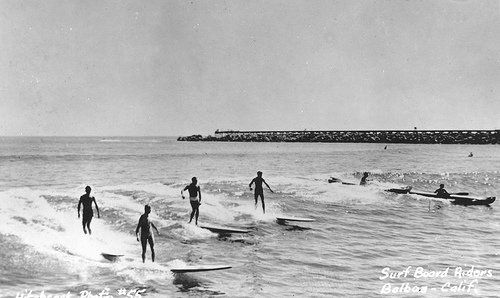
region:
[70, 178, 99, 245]
THIS IS A PERSON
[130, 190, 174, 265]
THIS IS A PERSON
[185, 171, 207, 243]
THIS IS A PERSON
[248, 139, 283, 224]
THIS IS A PERSON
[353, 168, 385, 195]
THIS IS A PERSON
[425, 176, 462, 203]
THIS IS A PERSON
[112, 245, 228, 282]
THAT IS A SURF BOARD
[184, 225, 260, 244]
THAT IS A SURF BOARD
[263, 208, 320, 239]
THAT IS A SURF BOARD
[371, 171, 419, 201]
THAT IS A SURF BOARD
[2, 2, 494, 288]
black and white filter.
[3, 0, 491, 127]
the sky is clear.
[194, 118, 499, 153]
bridge in the background.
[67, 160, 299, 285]
people standing on surf boards.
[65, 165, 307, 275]
people in the ocean.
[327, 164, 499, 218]
people are boating.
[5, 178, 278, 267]
the waves are white.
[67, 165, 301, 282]
four people are surfing.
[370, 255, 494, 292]
white text on the photo.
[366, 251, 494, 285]
text says surf board riders.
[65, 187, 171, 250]
surfers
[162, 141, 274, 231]
surfers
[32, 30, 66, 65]
white clouds in blue sky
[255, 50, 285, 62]
white clouds in blue sky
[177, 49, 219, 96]
white clouds in blue sky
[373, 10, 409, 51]
white clouds in blue sky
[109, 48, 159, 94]
white clouds in blue sky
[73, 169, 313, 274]
a group of surfboarders standing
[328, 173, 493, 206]
a long boat in the water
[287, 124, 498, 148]
a promontory in the distance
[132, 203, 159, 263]
a person on a surfboard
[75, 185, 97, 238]
a woman on a surfboard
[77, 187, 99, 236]
a person on her surfboard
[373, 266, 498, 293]
the photographer credit in the corner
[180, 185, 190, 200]
right arm of a surfer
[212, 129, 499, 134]
a railing on the edge of the promontory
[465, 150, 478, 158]
a person mostly submerged in the water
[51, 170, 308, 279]
Surfers in the water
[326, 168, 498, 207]
Boaters on the water also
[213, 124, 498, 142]
Wharf in the distance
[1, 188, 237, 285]
Breaking waves on the water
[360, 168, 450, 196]
Two boaters on the boat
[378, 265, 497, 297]
Sign on the right side at the bottom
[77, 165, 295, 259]
Four water surfers on the water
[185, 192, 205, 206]
One surfer has white shoes on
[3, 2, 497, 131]
Light grey skies over head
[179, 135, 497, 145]
Rocks along the wharf